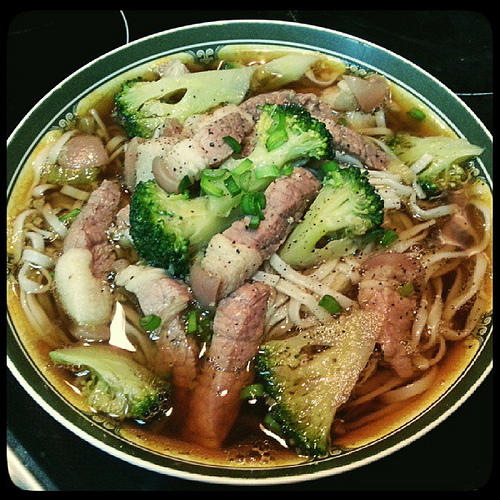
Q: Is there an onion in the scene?
A: Yes, there is an onion.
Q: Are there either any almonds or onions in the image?
A: Yes, there is an onion.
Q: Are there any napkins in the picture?
A: No, there are no napkins.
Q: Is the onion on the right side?
A: Yes, the onion is on the right of the image.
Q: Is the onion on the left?
A: No, the onion is on the right of the image.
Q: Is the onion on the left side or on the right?
A: The onion is on the right of the image.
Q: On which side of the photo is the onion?
A: The onion is on the right of the image.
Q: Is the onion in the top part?
A: Yes, the onion is in the top of the image.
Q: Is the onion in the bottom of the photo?
A: No, the onion is in the top of the image.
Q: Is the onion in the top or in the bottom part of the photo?
A: The onion is in the top of the image.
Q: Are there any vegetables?
A: Yes, there are vegetables.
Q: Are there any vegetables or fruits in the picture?
A: Yes, there are vegetables.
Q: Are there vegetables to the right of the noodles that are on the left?
A: Yes, there are vegetables to the right of the noodles.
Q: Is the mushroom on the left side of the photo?
A: Yes, the mushroom is on the left of the image.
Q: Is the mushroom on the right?
A: No, the mushroom is on the left of the image.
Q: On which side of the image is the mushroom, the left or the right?
A: The mushroom is on the left of the image.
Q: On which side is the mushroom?
A: The mushroom is on the left of the image.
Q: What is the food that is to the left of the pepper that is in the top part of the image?
A: The food is a mushroom.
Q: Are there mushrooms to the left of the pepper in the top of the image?
A: Yes, there is a mushroom to the left of the pepper.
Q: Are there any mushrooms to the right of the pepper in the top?
A: No, the mushroom is to the left of the pepper.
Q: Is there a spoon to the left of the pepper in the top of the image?
A: No, there is a mushroom to the left of the pepper.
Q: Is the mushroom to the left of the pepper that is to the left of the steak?
A: Yes, the mushroom is to the left of the pepper.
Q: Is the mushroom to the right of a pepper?
A: No, the mushroom is to the left of a pepper.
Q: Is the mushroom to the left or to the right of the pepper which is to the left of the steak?
A: The mushroom is to the left of the pepper.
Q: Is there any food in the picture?
A: Yes, there is food.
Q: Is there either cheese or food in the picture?
A: Yes, there is food.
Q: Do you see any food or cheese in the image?
A: Yes, there is food.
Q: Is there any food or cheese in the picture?
A: Yes, there is food.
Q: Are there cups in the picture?
A: No, there are no cups.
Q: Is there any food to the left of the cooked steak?
A: Yes, there is food to the left of the steak.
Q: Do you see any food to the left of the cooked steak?
A: Yes, there is food to the left of the steak.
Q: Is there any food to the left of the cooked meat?
A: Yes, there is food to the left of the steak.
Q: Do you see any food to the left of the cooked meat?
A: Yes, there is food to the left of the steak.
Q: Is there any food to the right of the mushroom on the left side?
A: Yes, there is food to the right of the mushroom.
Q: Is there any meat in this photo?
A: Yes, there is meat.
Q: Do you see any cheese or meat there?
A: Yes, there is meat.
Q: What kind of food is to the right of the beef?
A: The food is meat.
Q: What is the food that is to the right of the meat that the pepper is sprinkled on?
A: The food is meat.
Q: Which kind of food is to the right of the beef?
A: The food is meat.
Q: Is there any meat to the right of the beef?
A: Yes, there is meat to the right of the beef.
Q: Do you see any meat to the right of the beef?
A: Yes, there is meat to the right of the beef.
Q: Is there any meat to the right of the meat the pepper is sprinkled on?
A: Yes, there is meat to the right of the beef.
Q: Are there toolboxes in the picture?
A: No, there are no toolboxes.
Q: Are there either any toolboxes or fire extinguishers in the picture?
A: No, there are no toolboxes or fire extinguishers.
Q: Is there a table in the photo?
A: Yes, there is a table.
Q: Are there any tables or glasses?
A: Yes, there is a table.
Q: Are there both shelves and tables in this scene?
A: No, there is a table but no shelves.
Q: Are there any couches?
A: No, there are no couches.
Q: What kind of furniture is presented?
A: The furniture is a table.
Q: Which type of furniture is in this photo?
A: The furniture is a table.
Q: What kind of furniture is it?
A: The piece of furniture is a table.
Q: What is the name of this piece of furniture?
A: This is a table.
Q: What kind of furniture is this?
A: This is a table.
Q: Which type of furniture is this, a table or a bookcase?
A: This is a table.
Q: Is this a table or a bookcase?
A: This is a table.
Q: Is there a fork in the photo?
A: Yes, there is a fork.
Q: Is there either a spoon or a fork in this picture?
A: Yes, there is a fork.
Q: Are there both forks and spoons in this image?
A: No, there is a fork but no spoons.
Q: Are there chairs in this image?
A: No, there are no chairs.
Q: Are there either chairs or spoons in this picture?
A: No, there are no chairs or spoons.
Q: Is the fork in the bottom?
A: Yes, the fork is in the bottom of the image.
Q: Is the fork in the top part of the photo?
A: No, the fork is in the bottom of the image.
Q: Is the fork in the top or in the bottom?
A: The fork is in the bottom of the image.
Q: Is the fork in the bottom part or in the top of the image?
A: The fork is in the bottom of the image.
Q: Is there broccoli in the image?
A: Yes, there is broccoli.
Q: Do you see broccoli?
A: Yes, there is broccoli.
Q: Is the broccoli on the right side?
A: No, the broccoli is on the left of the image.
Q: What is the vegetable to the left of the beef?
A: The vegetable is broccoli.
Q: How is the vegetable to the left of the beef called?
A: The vegetable is broccoli.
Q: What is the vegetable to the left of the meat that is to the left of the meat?
A: The vegetable is broccoli.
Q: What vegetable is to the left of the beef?
A: The vegetable is broccoli.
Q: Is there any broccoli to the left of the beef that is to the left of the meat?
A: Yes, there is broccoli to the left of the beef.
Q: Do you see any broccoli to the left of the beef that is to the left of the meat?
A: Yes, there is broccoli to the left of the beef.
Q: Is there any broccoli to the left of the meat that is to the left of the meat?
A: Yes, there is broccoli to the left of the beef.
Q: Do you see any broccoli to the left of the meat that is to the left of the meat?
A: Yes, there is broccoli to the left of the beef.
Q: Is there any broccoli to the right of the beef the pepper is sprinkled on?
A: No, the broccoli is to the left of the beef.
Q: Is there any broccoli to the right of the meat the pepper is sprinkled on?
A: No, the broccoli is to the left of the beef.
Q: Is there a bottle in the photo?
A: No, there are no bottles.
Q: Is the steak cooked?
A: Yes, the steak is cooked.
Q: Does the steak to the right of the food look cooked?
A: Yes, the steak is cooked.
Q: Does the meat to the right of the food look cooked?
A: Yes, the steak is cooked.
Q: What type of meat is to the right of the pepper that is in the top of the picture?
A: The meat is a steak.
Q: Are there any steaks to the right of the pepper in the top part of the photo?
A: Yes, there is a steak to the right of the pepper.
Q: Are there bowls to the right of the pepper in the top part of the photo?
A: No, there is a steak to the right of the pepper.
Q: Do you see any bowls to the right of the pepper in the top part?
A: No, there is a steak to the right of the pepper.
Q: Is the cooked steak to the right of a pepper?
A: Yes, the steak is to the right of a pepper.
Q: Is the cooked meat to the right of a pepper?
A: Yes, the steak is to the right of a pepper.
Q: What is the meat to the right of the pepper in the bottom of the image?
A: The meat is beef.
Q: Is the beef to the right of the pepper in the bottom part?
A: Yes, the beef is to the right of the pepper.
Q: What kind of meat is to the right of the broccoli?
A: The meat is beef.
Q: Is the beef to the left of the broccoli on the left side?
A: No, the beef is to the right of the broccoli.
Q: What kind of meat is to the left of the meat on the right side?
A: The meat is beef.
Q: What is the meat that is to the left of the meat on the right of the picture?
A: The meat is beef.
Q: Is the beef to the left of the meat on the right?
A: Yes, the beef is to the left of the meat.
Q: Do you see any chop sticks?
A: No, there are no chop sticks.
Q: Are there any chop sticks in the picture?
A: No, there are no chop sticks.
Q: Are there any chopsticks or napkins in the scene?
A: No, there are no chopsticks or napkins.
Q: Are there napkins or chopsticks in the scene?
A: No, there are no chopsticks or napkins.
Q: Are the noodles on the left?
A: Yes, the noodles are on the left of the image.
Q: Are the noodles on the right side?
A: No, the noodles are on the left of the image.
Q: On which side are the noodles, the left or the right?
A: The noodles are on the left of the image.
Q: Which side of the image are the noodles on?
A: The noodles are on the left of the image.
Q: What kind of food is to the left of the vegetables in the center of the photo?
A: The food is noodles.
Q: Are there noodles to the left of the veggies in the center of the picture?
A: Yes, there are noodles to the left of the veggies.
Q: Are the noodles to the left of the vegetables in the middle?
A: Yes, the noodles are to the left of the veggies.